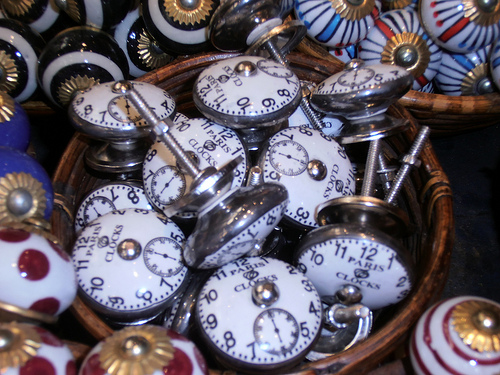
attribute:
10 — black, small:
[202, 285, 219, 304]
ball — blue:
[0, 147, 66, 234]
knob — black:
[187, 167, 302, 273]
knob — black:
[190, 253, 311, 355]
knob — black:
[73, 212, 200, 322]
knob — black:
[40, 32, 127, 97]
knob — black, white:
[324, 61, 427, 180]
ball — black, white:
[33, 21, 132, 117]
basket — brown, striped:
[418, 180, 483, 295]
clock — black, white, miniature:
[181, 46, 321, 143]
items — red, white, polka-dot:
[18, 50, 448, 369]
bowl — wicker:
[33, 33, 467, 372]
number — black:
[300, 301, 318, 336]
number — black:
[202, 312, 227, 334]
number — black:
[150, 271, 179, 290]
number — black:
[72, 256, 89, 272]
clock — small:
[68, 73, 175, 133]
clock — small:
[140, 116, 245, 213]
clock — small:
[259, 120, 353, 223]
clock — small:
[313, 62, 410, 108]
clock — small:
[188, 189, 290, 260]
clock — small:
[300, 227, 410, 307]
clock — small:
[198, 254, 320, 361]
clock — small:
[68, 210, 191, 310]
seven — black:
[241, 338, 265, 361]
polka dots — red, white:
[2, 222, 81, 319]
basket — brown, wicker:
[382, 126, 459, 355]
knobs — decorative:
[179, 103, 394, 288]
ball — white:
[0, 227, 78, 310]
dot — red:
[16, 246, 52, 282]